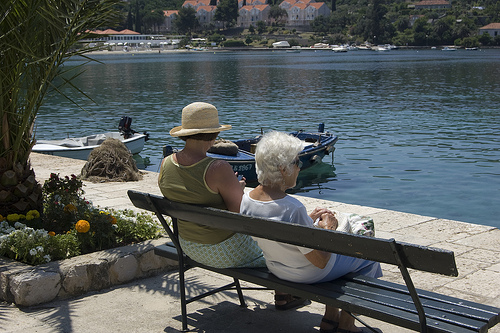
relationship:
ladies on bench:
[157, 103, 381, 331] [125, 189, 497, 330]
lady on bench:
[154, 101, 309, 310] [125, 189, 497, 330]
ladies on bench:
[236, 129, 384, 333] [125, 189, 497, 330]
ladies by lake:
[236, 129, 384, 333] [123, 26, 485, 196]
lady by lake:
[154, 101, 309, 310] [123, 26, 485, 196]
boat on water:
[47, 103, 182, 195] [63, 45, 498, 221]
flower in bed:
[4, 207, 24, 227] [0, 173, 185, 307]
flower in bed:
[21, 205, 42, 223] [0, 173, 185, 307]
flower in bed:
[70, 218, 95, 234] [0, 173, 185, 307]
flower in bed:
[41, 253, 57, 263] [0, 173, 185, 307]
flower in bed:
[26, 240, 33, 257] [0, 173, 185, 307]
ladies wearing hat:
[236, 129, 384, 333] [169, 95, 232, 135]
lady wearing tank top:
[125, 89, 255, 300] [158, 151, 239, 241]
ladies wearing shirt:
[236, 129, 384, 333] [235, 187, 338, 282]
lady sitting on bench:
[154, 101, 309, 310] [125, 189, 497, 330]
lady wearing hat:
[154, 101, 309, 310] [166, 93, 236, 150]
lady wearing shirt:
[154, 101, 309, 310] [160, 159, 224, 239]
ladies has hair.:
[236, 129, 384, 333] [250, 119, 303, 184]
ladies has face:
[236, 129, 384, 333] [286, 157, 303, 193]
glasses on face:
[281, 151, 298, 178] [286, 157, 303, 193]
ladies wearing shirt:
[236, 129, 384, 333] [241, 191, 337, 283]